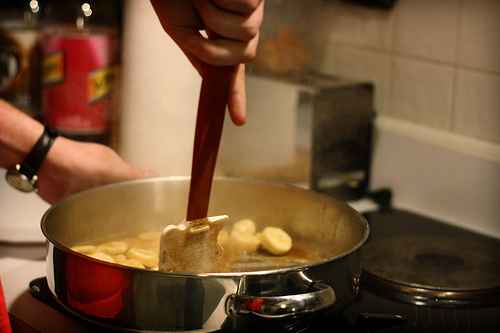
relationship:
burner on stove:
[364, 233, 497, 309] [28, 209, 499, 332]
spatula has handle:
[159, 64, 234, 274] [186, 66, 236, 221]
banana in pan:
[67, 219, 291, 272] [41, 174, 370, 331]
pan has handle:
[41, 174, 370, 331] [226, 280, 337, 320]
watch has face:
[6, 125, 58, 194] [6, 174, 35, 194]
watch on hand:
[6, 125, 58, 194] [5, 124, 160, 205]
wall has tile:
[246, 5, 498, 241] [245, 0, 498, 147]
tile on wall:
[245, 0, 498, 147] [246, 5, 498, 241]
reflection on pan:
[54, 247, 128, 321] [41, 174, 370, 331]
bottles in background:
[2, 0, 123, 147] [0, 0, 498, 208]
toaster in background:
[213, 69, 378, 201] [0, 0, 498, 208]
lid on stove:
[364, 233, 497, 309] [28, 209, 499, 332]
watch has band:
[6, 125, 58, 194] [20, 123, 59, 178]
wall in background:
[246, 5, 498, 241] [0, 0, 498, 208]